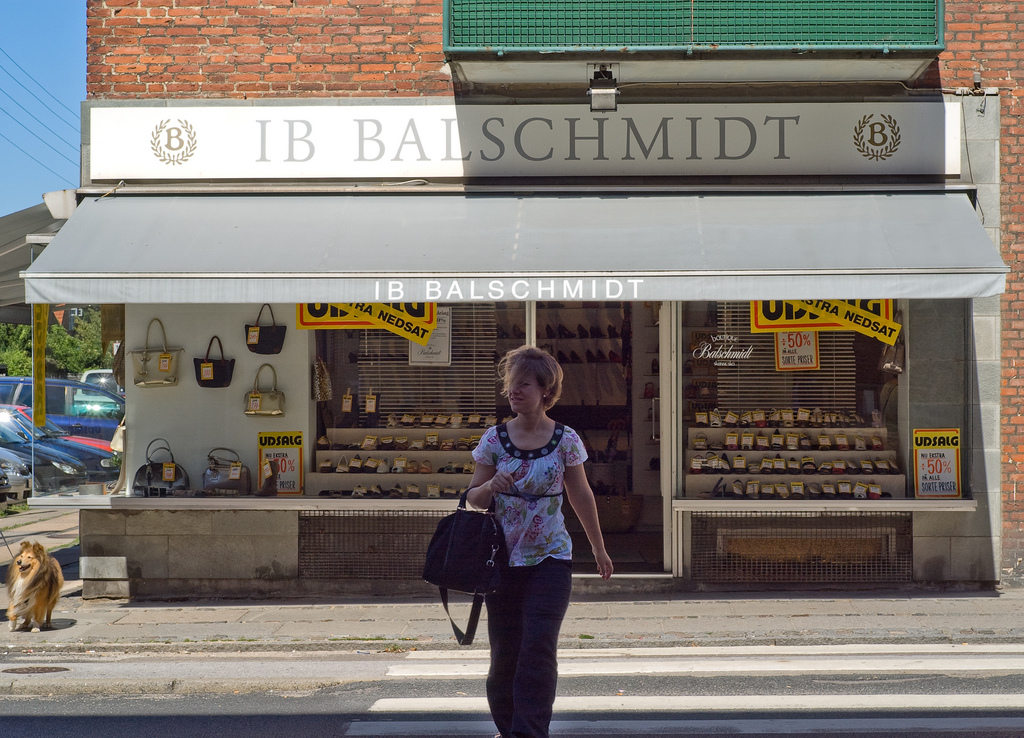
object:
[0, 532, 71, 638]
dog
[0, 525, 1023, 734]
sidewalk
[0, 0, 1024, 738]
picture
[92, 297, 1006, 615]
wall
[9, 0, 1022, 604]
building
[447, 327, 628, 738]
lady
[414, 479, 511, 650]
bag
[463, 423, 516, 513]
lady's arm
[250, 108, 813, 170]
sign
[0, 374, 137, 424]
car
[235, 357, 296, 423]
bag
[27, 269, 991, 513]
display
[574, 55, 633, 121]
light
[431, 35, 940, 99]
awning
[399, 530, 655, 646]
pants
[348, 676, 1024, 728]
lines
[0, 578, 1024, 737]
street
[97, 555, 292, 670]
no object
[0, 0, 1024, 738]
outdoors